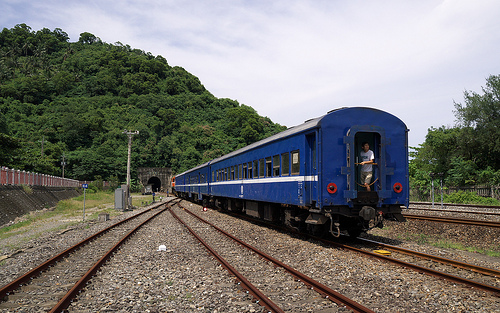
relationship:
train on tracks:
[167, 103, 419, 239] [0, 186, 498, 312]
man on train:
[357, 140, 376, 191] [167, 103, 419, 239]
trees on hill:
[0, 20, 301, 187] [0, 14, 340, 201]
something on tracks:
[370, 245, 391, 256] [0, 186, 498, 312]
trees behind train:
[0, 20, 301, 187] [167, 103, 419, 239]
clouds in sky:
[5, 0, 498, 145] [1, 1, 496, 169]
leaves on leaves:
[1, 23, 392, 196] [0, 20, 301, 187]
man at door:
[357, 140, 376, 191] [350, 132, 384, 190]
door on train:
[350, 132, 384, 190] [167, 103, 419, 239]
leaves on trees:
[1, 23, 392, 196] [0, 20, 301, 187]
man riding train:
[357, 140, 376, 191] [167, 103, 419, 239]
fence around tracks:
[378, 183, 499, 207] [0, 186, 498, 312]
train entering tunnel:
[167, 103, 419, 239] [138, 164, 179, 193]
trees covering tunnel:
[0, 20, 301, 187] [138, 164, 179, 193]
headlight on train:
[326, 181, 339, 194] [167, 103, 419, 239]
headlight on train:
[392, 182, 403, 193] [167, 103, 419, 239]